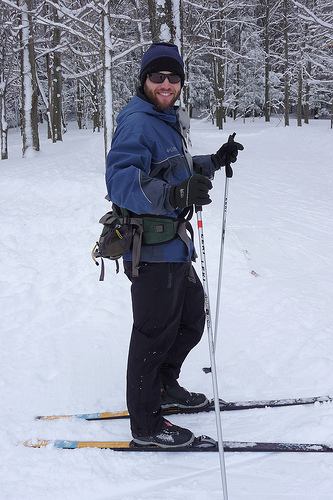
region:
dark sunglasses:
[143, 70, 182, 86]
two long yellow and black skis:
[26, 393, 332, 455]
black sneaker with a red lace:
[128, 413, 197, 448]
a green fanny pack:
[88, 192, 194, 278]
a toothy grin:
[157, 90, 175, 97]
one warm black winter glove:
[167, 167, 214, 210]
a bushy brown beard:
[140, 74, 186, 116]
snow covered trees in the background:
[1, 1, 332, 163]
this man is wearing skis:
[93, 41, 250, 469]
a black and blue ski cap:
[135, 39, 187, 84]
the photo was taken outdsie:
[2, 5, 328, 499]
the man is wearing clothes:
[73, 10, 223, 498]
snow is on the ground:
[261, 139, 332, 265]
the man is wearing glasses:
[131, 47, 217, 125]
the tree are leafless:
[9, 4, 323, 41]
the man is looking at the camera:
[122, 49, 210, 117]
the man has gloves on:
[163, 128, 261, 225]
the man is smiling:
[142, 71, 205, 119]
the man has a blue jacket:
[90, 103, 216, 269]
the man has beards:
[134, 51, 201, 133]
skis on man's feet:
[23, 396, 332, 451]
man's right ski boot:
[129, 425, 195, 449]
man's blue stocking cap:
[137, 42, 185, 90]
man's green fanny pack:
[132, 214, 176, 246]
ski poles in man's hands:
[194, 132, 236, 498]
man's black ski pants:
[122, 260, 205, 439]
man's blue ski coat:
[105, 89, 219, 260]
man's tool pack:
[92, 212, 133, 282]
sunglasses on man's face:
[144, 70, 183, 84]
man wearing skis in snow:
[23, 41, 331, 453]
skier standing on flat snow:
[51, 4, 291, 470]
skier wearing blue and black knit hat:
[108, 11, 199, 109]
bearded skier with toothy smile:
[111, 28, 208, 116]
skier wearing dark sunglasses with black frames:
[138, 60, 190, 87]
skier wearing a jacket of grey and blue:
[72, 76, 251, 273]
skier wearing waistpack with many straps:
[84, 196, 209, 285]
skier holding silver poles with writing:
[184, 138, 251, 481]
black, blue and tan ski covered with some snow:
[26, 381, 319, 461]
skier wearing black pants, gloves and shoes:
[84, 29, 264, 450]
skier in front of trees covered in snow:
[11, 13, 314, 121]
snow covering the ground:
[3, 245, 90, 379]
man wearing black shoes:
[134, 383, 204, 443]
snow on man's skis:
[230, 373, 325, 459]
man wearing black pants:
[125, 264, 203, 394]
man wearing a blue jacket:
[100, 100, 180, 257]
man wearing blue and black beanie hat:
[134, 37, 185, 71]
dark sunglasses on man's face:
[140, 69, 184, 88]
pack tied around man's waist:
[85, 200, 201, 278]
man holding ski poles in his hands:
[190, 128, 242, 499]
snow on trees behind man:
[2, 1, 327, 145]